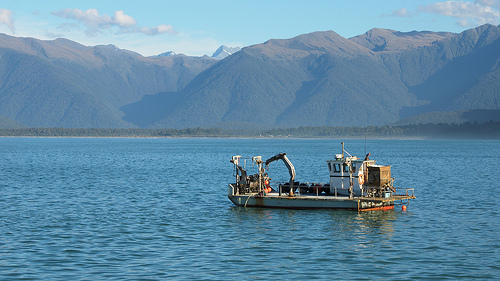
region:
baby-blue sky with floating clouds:
[1, 3, 497, 59]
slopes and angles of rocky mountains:
[0, 20, 495, 121]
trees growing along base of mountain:
[0, 125, 492, 135]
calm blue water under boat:
[0, 137, 495, 272]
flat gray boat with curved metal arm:
[221, 145, 412, 207]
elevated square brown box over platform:
[361, 162, 391, 207]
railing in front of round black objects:
[280, 177, 365, 192]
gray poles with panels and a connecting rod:
[225, 150, 262, 190]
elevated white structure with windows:
[325, 151, 365, 196]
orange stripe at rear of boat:
[357, 200, 394, 215]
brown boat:
[176, 140, 405, 222]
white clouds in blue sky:
[17, 15, 62, 45]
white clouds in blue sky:
[416, 25, 498, 46]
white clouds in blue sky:
[384, 15, 432, 52]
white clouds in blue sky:
[324, 6, 362, 48]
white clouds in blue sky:
[242, 21, 293, 51]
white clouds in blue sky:
[164, 15, 201, 42]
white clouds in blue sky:
[97, 0, 146, 52]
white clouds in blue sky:
[77, 23, 107, 47]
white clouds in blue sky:
[177, 11, 219, 47]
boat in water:
[210, 146, 410, 225]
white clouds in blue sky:
[47, 14, 88, 34]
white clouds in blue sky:
[172, 12, 189, 31]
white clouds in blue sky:
[113, 8, 158, 35]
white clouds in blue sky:
[18, 5, 48, 25]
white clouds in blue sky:
[297, 3, 324, 27]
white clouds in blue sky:
[370, 5, 398, 25]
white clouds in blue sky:
[413, 3, 445, 27]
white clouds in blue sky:
[224, 0, 268, 30]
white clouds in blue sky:
[26, 19, 78, 49]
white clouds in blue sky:
[392, 26, 421, 53]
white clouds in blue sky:
[405, 2, 458, 52]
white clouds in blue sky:
[270, 15, 307, 49]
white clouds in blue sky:
[341, 5, 403, 41]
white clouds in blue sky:
[168, 24, 232, 61]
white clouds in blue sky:
[270, 55, 300, 72]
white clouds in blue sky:
[142, 23, 212, 64]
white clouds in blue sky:
[82, 22, 138, 51]